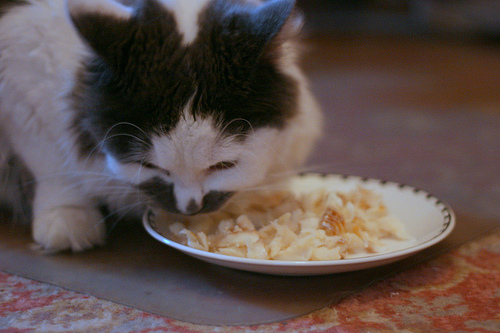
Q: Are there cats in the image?
A: Yes, there is a cat.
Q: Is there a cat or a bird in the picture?
A: Yes, there is a cat.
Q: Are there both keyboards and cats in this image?
A: No, there is a cat but no keyboards.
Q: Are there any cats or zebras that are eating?
A: Yes, the cat is eating.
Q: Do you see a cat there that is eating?
A: Yes, there is a cat that is eating.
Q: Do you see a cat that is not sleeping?
A: Yes, there is a cat that is eating .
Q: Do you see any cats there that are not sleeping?
A: Yes, there is a cat that is eating .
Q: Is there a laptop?
A: No, there are no laptops.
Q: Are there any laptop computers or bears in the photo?
A: No, there are no laptop computers or bears.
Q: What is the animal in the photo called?
A: The animal is a cat.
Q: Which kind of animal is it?
A: The animal is a cat.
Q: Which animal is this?
A: This is a cat.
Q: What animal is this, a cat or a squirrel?
A: This is a cat.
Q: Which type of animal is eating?
A: The animal is a cat.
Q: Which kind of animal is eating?
A: The animal is a cat.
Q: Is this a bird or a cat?
A: This is a cat.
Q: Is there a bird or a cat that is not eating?
A: No, there is a cat but it is eating.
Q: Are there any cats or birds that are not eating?
A: No, there is a cat but it is eating.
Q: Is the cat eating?
A: Yes, the cat is eating.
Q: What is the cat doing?
A: The cat is eating.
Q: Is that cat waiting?
A: No, the cat is eating.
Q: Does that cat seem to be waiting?
A: No, the cat is eating.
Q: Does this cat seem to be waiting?
A: No, the cat is eating.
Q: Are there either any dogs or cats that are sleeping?
A: No, there is a cat but it is eating.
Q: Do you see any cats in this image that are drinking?
A: No, there is a cat but it is eating.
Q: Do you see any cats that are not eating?
A: No, there is a cat but it is eating.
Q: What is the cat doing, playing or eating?
A: The cat is eating.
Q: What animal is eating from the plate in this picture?
A: The cat is eating from the plate.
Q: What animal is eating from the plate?
A: The cat is eating from the plate.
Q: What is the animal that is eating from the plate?
A: The animal is a cat.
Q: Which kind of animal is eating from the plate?
A: The animal is a cat.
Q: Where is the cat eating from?
A: The cat is eating from the plate.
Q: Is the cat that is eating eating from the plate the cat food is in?
A: Yes, the cat is eating from the plate.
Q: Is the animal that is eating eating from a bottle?
A: No, the cat is eating from the plate.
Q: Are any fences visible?
A: No, there are no fences.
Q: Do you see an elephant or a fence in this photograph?
A: No, there are no fences or elephants.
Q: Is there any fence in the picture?
A: No, there are no fences.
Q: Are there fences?
A: No, there are no fences.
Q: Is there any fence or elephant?
A: No, there are no fences or elephants.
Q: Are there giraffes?
A: No, there are no giraffes.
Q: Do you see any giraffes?
A: No, there are no giraffes.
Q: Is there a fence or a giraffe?
A: No, there are no giraffes or fences.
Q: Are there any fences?
A: No, there are no fences.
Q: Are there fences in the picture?
A: No, there are no fences.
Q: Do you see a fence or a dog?
A: No, there are no fences or dogs.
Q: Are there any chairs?
A: No, there are no chairs.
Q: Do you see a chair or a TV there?
A: No, there are no chairs or televisions.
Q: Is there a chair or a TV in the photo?
A: No, there are no chairs or televisions.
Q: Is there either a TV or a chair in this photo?
A: No, there are no chairs or televisions.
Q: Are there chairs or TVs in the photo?
A: No, there are no chairs or tvs.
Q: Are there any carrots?
A: No, there are no carrots.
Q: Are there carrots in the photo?
A: No, there are no carrots.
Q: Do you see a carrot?
A: No, there are no carrots.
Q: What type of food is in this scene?
A: The food is cat food.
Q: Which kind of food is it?
A: The food is cat food.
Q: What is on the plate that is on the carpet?
A: The cat food is on the plate.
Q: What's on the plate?
A: The cat food is on the plate.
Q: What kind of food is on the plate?
A: The food is cat food.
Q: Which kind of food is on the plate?
A: The food is cat food.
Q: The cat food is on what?
A: The cat food is on the plate.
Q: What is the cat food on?
A: The cat food is on the plate.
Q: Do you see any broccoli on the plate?
A: No, there is cat food on the plate.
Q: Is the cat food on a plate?
A: Yes, the cat food is on a plate.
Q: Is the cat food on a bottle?
A: No, the cat food is on a plate.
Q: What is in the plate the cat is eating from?
A: The cat food is in the plate.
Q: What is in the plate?
A: The cat food is in the plate.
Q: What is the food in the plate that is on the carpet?
A: The food is cat food.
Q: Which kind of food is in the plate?
A: The food is cat food.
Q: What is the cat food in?
A: The cat food is in the plate.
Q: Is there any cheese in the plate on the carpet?
A: No, there is cat food in the plate.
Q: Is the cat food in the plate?
A: Yes, the cat food is in the plate.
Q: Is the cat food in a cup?
A: No, the cat food is in the plate.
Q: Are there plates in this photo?
A: Yes, there is a plate.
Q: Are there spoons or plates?
A: Yes, there is a plate.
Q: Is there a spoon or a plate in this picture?
A: Yes, there is a plate.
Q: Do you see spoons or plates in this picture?
A: Yes, there is a plate.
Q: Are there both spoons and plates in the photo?
A: No, there is a plate but no spoons.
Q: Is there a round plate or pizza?
A: Yes, there is a round plate.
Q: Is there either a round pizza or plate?
A: Yes, there is a round plate.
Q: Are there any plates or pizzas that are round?
A: Yes, the plate is round.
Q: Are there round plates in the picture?
A: Yes, there is a round plate.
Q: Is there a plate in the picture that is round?
A: Yes, there is a plate that is round.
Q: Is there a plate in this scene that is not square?
A: Yes, there is a round plate.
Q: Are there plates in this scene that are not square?
A: Yes, there is a round plate.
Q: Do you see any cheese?
A: No, there is no cheese.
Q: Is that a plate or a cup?
A: That is a plate.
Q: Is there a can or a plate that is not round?
A: No, there is a plate but it is round.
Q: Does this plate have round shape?
A: Yes, the plate is round.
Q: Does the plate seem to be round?
A: Yes, the plate is round.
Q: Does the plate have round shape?
A: Yes, the plate is round.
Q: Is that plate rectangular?
A: No, the plate is round.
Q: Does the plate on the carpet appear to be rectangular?
A: No, the plate is round.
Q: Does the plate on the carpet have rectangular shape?
A: No, the plate is round.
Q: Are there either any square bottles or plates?
A: No, there is a plate but it is round.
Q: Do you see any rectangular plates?
A: No, there is a plate but it is round.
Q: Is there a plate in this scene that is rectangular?
A: No, there is a plate but it is round.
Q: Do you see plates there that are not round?
A: No, there is a plate but it is round.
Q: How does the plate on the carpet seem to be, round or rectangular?
A: The plate is round.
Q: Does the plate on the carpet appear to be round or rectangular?
A: The plate is round.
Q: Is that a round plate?
A: Yes, that is a round plate.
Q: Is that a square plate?
A: No, that is a round plate.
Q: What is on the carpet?
A: The plate is on the carpet.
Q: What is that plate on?
A: The plate is on the carpet.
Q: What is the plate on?
A: The plate is on the carpet.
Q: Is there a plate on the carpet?
A: Yes, there is a plate on the carpet.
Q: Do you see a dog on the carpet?
A: No, there is a plate on the carpet.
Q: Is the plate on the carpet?
A: Yes, the plate is on the carpet.